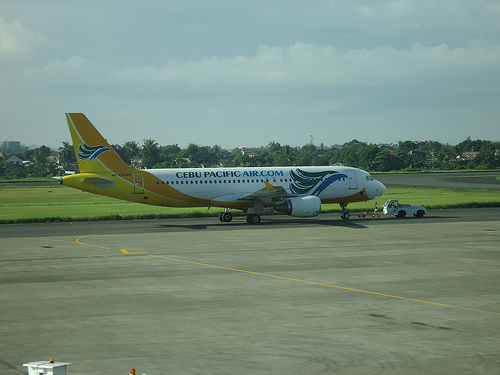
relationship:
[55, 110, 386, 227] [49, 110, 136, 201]
plane has tail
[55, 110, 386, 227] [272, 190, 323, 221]
plane has engine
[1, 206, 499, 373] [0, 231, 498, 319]
pavement has lines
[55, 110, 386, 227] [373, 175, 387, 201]
plane has nose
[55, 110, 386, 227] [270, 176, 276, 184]
plane has windows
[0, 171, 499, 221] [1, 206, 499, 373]
grass by pavement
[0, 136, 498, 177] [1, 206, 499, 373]
trees are by pavement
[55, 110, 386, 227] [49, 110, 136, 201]
plane has a tail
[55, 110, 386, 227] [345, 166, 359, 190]
plane has door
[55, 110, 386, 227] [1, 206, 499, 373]
plane on pavement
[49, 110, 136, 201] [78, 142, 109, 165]
tail has logo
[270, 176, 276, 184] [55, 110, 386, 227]
windows are on a plane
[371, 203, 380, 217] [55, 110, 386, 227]
person walking next to plane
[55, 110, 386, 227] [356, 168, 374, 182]
plane has cock pit